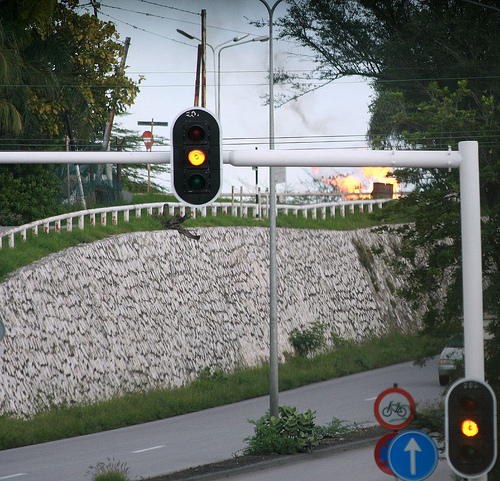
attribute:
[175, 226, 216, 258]
tomato — cut up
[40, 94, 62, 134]
flowers — GREEN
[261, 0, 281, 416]
gray pole — BASE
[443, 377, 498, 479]
stop light — BLACK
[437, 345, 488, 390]
car — DRIVING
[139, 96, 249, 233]
light — BLACK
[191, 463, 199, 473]
tomato — cut up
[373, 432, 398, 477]
sign — RED, BLUE, CIRCLE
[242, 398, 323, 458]
bush — SMALL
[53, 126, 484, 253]
pole — LIGHT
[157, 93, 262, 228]
light — YELLOW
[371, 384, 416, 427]
sign — RED, WHITE, BLACK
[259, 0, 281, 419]
pole — tall, grey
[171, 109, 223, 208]
light — YELLOW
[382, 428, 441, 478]
sign — BLUE, WHITE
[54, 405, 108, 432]
grass — GREEN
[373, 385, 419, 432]
sign — BIKE, RED, WHITE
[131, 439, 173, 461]
stripe — WHITE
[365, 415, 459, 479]
sign — BLUE, circular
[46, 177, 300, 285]
guard — WHITE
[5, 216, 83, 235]
fence — WHITE, SHORT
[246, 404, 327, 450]
leaves — GREEN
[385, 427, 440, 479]
sign — BLUE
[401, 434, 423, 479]
arrow — WHITE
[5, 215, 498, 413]
wall — ROCK, GREY, STONE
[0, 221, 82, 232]
road — another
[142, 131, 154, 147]
sign — red, stop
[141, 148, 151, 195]
pole — wood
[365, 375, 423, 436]
sign — cirle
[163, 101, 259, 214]
light — YELLOW, LIT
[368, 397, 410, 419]
sign — red and white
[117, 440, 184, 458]
lines — WHITE